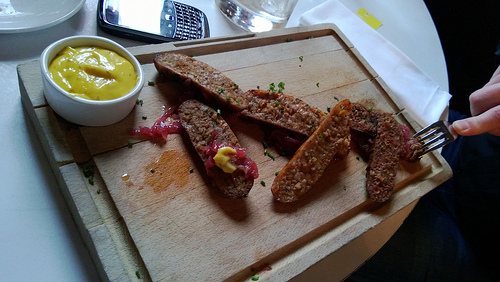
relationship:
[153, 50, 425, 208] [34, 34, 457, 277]
brown meat on cutting board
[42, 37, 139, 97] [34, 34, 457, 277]
mustard on cutting board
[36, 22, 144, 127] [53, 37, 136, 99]
white dish filled with yellow sauce